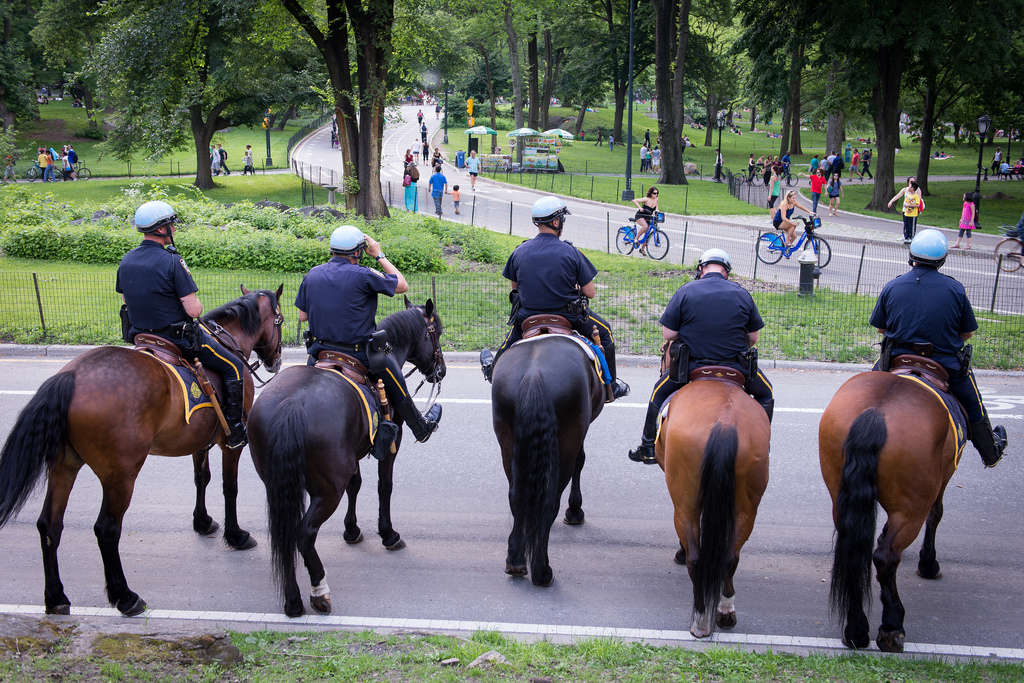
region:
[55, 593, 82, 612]
hoof of the horse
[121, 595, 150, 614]
hoof of the horse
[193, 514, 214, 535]
hoof of the horse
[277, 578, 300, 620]
hoof of the horse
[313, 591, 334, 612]
hoof of the horse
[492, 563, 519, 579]
hoof of the horse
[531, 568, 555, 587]
hoof of the horse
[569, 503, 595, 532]
hoof of the horse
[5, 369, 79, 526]
black tail on horse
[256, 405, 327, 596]
black tail on horse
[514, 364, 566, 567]
black tail on horse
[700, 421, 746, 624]
black tail on horse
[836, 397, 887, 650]
black tail on horse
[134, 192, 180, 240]
helmet on man's head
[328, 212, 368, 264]
helmet on cop's head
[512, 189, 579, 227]
helmet on cops head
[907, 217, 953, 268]
helmet on man's head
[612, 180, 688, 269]
woman riding a bike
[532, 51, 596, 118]
green leaves on the tree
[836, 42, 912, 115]
green leaves on the tree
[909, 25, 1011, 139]
green leaves on the tree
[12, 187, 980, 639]
fives horses on the road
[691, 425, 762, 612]
black tail on a horse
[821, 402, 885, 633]
black tail on a horse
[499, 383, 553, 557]
black tail on a horse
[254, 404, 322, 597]
black tail on a horse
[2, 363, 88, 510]
black tail on a horse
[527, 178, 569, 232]
helmet on an officer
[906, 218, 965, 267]
helmet on an officer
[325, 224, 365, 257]
helmet on an officer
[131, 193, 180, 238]
helmet on an officer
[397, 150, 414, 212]
person on the street in the park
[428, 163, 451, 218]
person on the street in the park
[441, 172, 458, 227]
person on the street in the park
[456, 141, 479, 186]
person on the street in the park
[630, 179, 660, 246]
person on the street in the park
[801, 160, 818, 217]
person on the street in the park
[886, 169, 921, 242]
person on the street in the park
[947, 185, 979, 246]
person on the street in the park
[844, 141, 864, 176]
person on the street in the park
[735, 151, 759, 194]
person on the street in the park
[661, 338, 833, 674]
horse is light brown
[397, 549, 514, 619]
road is dark grey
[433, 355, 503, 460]
white line on road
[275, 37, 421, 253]
brown tree with forked trunk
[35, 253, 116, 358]
fence is behind horses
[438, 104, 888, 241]
people are riding bikes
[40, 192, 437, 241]
green bushes near tree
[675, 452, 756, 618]
horse has black tail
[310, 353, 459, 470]
black and gold cloth on horse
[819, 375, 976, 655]
the back of a brown and black horse